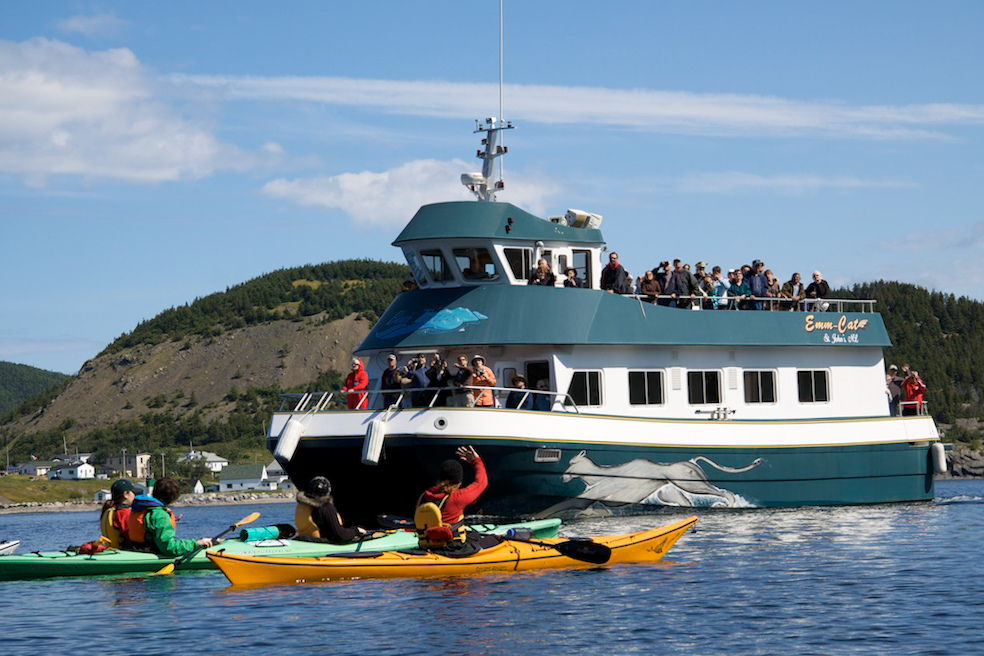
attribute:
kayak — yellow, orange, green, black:
[207, 518, 700, 593]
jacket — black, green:
[126, 496, 204, 559]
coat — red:
[341, 358, 372, 399]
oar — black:
[157, 511, 265, 579]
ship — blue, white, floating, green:
[263, 116, 952, 518]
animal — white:
[549, 442, 762, 517]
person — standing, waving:
[465, 353, 502, 405]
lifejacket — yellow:
[295, 500, 346, 539]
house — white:
[47, 459, 100, 481]